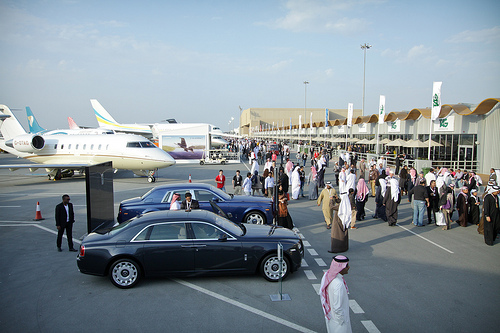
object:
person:
[53, 194, 79, 252]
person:
[318, 255, 350, 333]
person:
[215, 169, 227, 190]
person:
[409, 177, 432, 227]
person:
[232, 170, 244, 196]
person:
[426, 180, 439, 224]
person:
[377, 180, 404, 230]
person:
[480, 184, 500, 246]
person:
[182, 192, 199, 209]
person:
[168, 191, 184, 210]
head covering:
[320, 253, 346, 314]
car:
[78, 200, 306, 288]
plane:
[0, 105, 177, 183]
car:
[115, 183, 275, 227]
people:
[325, 190, 353, 254]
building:
[226, 99, 499, 207]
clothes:
[319, 272, 353, 332]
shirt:
[215, 174, 226, 187]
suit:
[55, 202, 75, 248]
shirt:
[63, 204, 71, 221]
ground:
[2, 163, 500, 331]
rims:
[263, 257, 287, 282]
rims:
[112, 261, 138, 285]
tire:
[259, 252, 290, 282]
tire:
[106, 256, 141, 289]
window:
[126, 140, 141, 149]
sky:
[0, 2, 499, 134]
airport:
[0, 80, 499, 332]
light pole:
[357, 42, 372, 114]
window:
[53, 143, 58, 150]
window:
[60, 144, 65, 151]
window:
[68, 143, 72, 149]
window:
[82, 142, 87, 151]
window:
[75, 142, 80, 150]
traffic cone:
[33, 201, 46, 221]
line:
[176, 278, 317, 332]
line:
[35, 225, 83, 244]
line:
[0, 204, 22, 210]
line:
[395, 222, 455, 254]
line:
[364, 207, 375, 215]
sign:
[271, 242, 291, 301]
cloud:
[266, 1, 368, 37]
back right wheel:
[107, 256, 143, 289]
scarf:
[487, 185, 500, 196]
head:
[487, 185, 499, 195]